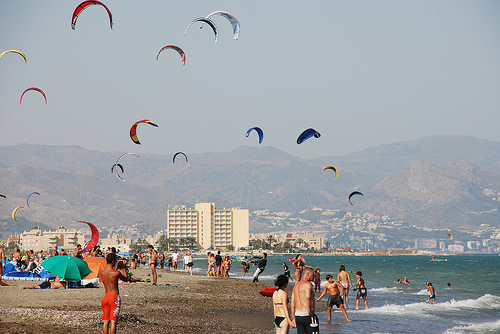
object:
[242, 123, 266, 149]
kite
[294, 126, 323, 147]
kite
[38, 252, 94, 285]
umbrella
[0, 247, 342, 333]
beach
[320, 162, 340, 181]
kite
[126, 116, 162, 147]
kite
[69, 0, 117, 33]
kite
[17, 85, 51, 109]
kite